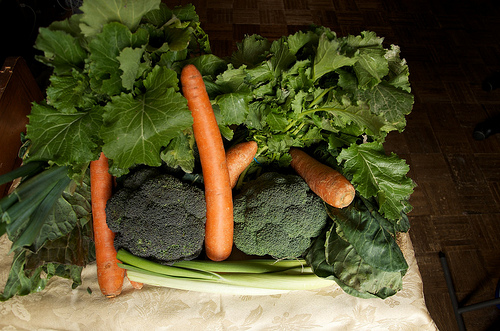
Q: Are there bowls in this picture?
A: No, there are no bowls.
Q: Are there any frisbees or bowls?
A: No, there are no bowls or frisbees.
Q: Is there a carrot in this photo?
A: Yes, there is a carrot.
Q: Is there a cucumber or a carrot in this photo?
A: Yes, there is a carrot.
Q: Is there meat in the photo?
A: No, there is no meat.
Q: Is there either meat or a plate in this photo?
A: No, there are no meat or plates.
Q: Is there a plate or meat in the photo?
A: No, there are no meat or plates.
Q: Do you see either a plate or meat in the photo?
A: No, there are no meat or plates.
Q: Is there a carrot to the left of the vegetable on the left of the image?
A: No, the carrot is to the right of the vegetable.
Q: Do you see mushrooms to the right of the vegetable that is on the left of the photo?
A: No, there is a carrot to the right of the vegetable.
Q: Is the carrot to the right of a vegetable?
A: Yes, the carrot is to the right of a vegetable.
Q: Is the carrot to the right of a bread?
A: No, the carrot is to the right of a vegetable.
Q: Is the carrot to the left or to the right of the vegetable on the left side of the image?
A: The carrot is to the right of the vegetable.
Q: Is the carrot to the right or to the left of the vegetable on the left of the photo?
A: The carrot is to the right of the vegetable.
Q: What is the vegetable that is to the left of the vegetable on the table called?
A: The vegetable is a carrot.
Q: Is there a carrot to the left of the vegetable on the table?
A: Yes, there is a carrot to the left of the vegetable.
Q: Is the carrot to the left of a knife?
A: No, the carrot is to the left of the vegetable.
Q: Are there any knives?
A: No, there are no knives.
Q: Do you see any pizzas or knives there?
A: No, there are no knives or pizzas.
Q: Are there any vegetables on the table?
A: Yes, there is a vegetable on the table.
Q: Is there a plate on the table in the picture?
A: No, there is a vegetable on the table.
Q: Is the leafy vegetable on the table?
A: Yes, the vegetable is on the table.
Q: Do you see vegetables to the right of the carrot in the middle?
A: Yes, there is a vegetable to the right of the carrot.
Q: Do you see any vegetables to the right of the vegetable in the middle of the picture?
A: Yes, there is a vegetable to the right of the carrot.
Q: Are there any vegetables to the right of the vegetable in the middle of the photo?
A: Yes, there is a vegetable to the right of the carrot.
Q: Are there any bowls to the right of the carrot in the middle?
A: No, there is a vegetable to the right of the carrot.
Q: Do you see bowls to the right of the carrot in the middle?
A: No, there is a vegetable to the right of the carrot.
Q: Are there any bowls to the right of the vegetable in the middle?
A: No, there is a vegetable to the right of the carrot.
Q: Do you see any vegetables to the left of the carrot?
A: Yes, there is a vegetable to the left of the carrot.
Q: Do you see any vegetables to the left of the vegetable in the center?
A: Yes, there is a vegetable to the left of the carrot.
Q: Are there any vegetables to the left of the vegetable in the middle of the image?
A: Yes, there is a vegetable to the left of the carrot.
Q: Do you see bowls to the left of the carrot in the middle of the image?
A: No, there is a vegetable to the left of the carrot.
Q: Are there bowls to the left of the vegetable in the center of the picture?
A: No, there is a vegetable to the left of the carrot.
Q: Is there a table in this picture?
A: Yes, there is a table.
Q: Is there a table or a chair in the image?
A: Yes, there is a table.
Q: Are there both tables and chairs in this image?
A: No, there is a table but no chairs.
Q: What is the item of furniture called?
A: The piece of furniture is a table.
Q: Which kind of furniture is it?
A: The piece of furniture is a table.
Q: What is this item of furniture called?
A: This is a table.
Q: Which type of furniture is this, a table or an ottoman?
A: This is a table.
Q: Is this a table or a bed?
A: This is a table.